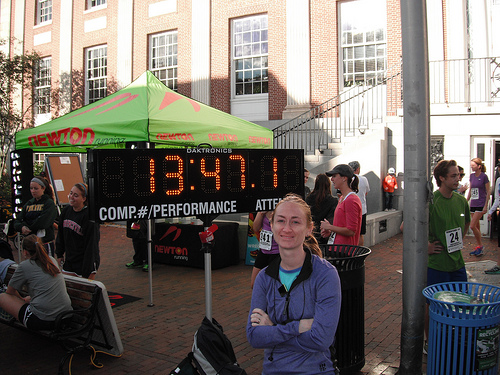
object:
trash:
[422, 282, 500, 374]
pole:
[400, 0, 430, 374]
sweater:
[247, 247, 342, 375]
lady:
[0, 233, 74, 332]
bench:
[6, 266, 123, 372]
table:
[71, 269, 122, 358]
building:
[0, 0, 500, 238]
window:
[230, 14, 268, 99]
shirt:
[427, 190, 471, 271]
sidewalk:
[119, 266, 260, 370]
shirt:
[259, 202, 280, 254]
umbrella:
[16, 67, 275, 150]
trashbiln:
[309, 244, 369, 373]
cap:
[325, 164, 353, 178]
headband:
[31, 177, 46, 188]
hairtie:
[35, 242, 38, 244]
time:
[150, 155, 278, 196]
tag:
[445, 228, 463, 253]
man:
[422, 160, 469, 349]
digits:
[149, 156, 184, 196]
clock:
[88, 146, 304, 224]